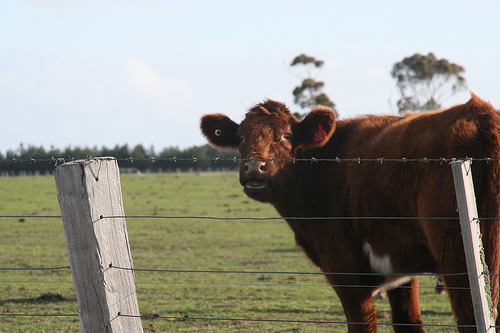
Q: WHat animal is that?
A: Cow.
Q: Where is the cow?
A: In a pasture.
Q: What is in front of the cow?
A: A fence.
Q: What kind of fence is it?
A: A barbed wire.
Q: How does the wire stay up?
A: Posts.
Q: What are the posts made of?
A: Wood.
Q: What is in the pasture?
A: Grass.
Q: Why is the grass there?
A: For the cow.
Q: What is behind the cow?
A: Trees.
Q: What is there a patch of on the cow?
A: White fur.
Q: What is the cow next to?
A: Barbed wire.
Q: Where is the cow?
A: In a field.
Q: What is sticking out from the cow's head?
A: It's large ears.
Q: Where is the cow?
A: In a large field.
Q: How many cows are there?
A: One.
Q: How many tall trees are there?
A: Two.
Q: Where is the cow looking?
A: At the camera.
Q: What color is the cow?
A: Brown.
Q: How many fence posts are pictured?
A: Two.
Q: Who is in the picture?
A: A cow.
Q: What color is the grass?
A: Green.